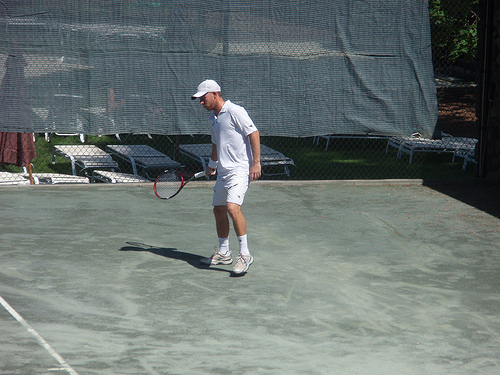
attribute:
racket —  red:
[146, 157, 211, 207]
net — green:
[2, 1, 443, 147]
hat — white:
[177, 62, 232, 106]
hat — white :
[185, 82, 223, 96]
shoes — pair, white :
[200, 254, 259, 276]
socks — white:
[217, 232, 249, 257]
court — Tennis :
[8, 188, 498, 373]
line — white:
[1, 297, 75, 371]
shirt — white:
[204, 99, 260, 172]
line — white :
[9, 298, 55, 358]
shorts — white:
[210, 156, 253, 214]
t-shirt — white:
[202, 103, 252, 171]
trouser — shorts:
[205, 166, 247, 209]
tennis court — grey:
[5, 179, 493, 371]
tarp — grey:
[1, 1, 498, 138]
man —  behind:
[189, 77, 262, 276]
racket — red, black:
[152, 166, 205, 198]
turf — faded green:
[3, 178, 499, 373]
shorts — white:
[197, 169, 259, 214]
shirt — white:
[212, 103, 253, 168]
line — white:
[0, 294, 81, 374]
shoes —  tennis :
[201, 252, 252, 275]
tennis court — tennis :
[16, 116, 498, 346]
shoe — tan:
[231, 252, 253, 274]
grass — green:
[290, 145, 450, 180]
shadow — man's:
[117, 237, 212, 278]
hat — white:
[194, 76, 224, 96]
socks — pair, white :
[216, 227, 253, 256]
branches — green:
[440, 19, 470, 58]